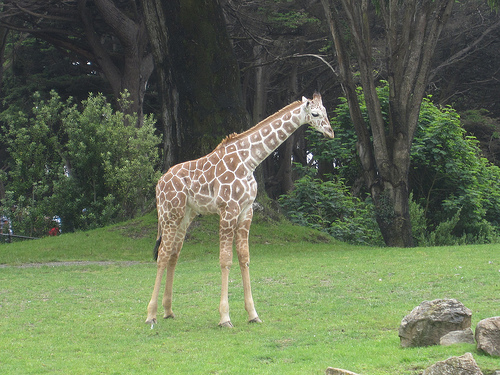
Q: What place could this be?
A: It is a zoo.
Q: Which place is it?
A: It is a zoo.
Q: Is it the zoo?
A: Yes, it is the zoo.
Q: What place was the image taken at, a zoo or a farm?
A: It was taken at a zoo.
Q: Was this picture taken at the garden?
A: No, the picture was taken in the zoo.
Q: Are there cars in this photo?
A: No, there are no cars.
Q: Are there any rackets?
A: No, there are no rackets.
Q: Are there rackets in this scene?
A: No, there are no rackets.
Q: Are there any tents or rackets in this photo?
A: No, there are no rackets or tents.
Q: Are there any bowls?
A: No, there are no bowls.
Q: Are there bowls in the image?
A: No, there are no bowls.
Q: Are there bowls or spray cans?
A: No, there are no bowls or spray cans.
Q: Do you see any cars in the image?
A: No, there are no cars.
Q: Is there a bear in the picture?
A: No, there are no bears.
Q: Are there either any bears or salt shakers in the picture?
A: No, there are no bears or salt shakers.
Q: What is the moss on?
A: The moss is on the tree.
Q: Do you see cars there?
A: No, there are no cars.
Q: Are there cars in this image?
A: No, there are no cars.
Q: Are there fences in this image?
A: Yes, there is a fence.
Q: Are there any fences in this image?
A: Yes, there is a fence.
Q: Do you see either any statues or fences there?
A: Yes, there is a fence.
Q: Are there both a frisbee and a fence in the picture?
A: No, there is a fence but no frisbees.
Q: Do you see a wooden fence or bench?
A: Yes, there is a wood fence.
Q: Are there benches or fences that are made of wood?
A: Yes, the fence is made of wood.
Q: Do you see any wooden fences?
A: Yes, there is a wood fence.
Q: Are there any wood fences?
A: Yes, there is a wood fence.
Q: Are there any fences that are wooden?
A: Yes, there is a fence that is wooden.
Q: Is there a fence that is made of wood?
A: Yes, there is a fence that is made of wood.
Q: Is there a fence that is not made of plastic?
A: Yes, there is a fence that is made of wood.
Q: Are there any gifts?
A: No, there are no gifts.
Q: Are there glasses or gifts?
A: No, there are no gifts or glasses.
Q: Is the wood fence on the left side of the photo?
A: Yes, the fence is on the left of the image.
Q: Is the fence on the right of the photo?
A: No, the fence is on the left of the image.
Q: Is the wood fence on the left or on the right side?
A: The fence is on the left of the image.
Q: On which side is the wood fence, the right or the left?
A: The fence is on the left of the image.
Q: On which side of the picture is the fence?
A: The fence is on the left of the image.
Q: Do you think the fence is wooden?
A: Yes, the fence is wooden.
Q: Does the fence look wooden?
A: Yes, the fence is wooden.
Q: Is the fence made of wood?
A: Yes, the fence is made of wood.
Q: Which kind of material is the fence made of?
A: The fence is made of wood.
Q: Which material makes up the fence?
A: The fence is made of wood.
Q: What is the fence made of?
A: The fence is made of wood.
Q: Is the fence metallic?
A: No, the fence is wooden.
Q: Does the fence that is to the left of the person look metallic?
A: No, the fence is wooden.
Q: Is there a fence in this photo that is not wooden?
A: No, there is a fence but it is wooden.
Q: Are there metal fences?
A: No, there is a fence but it is made of wood.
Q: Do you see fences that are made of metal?
A: No, there is a fence but it is made of wood.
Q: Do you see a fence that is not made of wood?
A: No, there is a fence but it is made of wood.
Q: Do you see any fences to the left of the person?
A: Yes, there is a fence to the left of the person.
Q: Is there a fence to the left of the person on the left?
A: Yes, there is a fence to the left of the person.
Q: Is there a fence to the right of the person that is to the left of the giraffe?
A: No, the fence is to the left of the person.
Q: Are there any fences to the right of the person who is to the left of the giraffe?
A: No, the fence is to the left of the person.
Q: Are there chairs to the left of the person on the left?
A: No, there is a fence to the left of the person.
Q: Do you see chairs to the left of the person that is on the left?
A: No, there is a fence to the left of the person.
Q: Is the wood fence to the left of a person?
A: Yes, the fence is to the left of a person.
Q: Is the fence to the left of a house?
A: No, the fence is to the left of a person.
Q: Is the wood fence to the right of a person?
A: No, the fence is to the left of a person.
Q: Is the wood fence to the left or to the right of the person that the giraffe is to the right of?
A: The fence is to the left of the person.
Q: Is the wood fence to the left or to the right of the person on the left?
A: The fence is to the left of the person.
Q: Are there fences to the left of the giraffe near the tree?
A: Yes, there is a fence to the left of the giraffe.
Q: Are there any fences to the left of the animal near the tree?
A: Yes, there is a fence to the left of the giraffe.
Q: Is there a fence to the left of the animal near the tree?
A: Yes, there is a fence to the left of the giraffe.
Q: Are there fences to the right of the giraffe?
A: No, the fence is to the left of the giraffe.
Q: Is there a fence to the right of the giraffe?
A: No, the fence is to the left of the giraffe.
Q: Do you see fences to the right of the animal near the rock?
A: No, the fence is to the left of the giraffe.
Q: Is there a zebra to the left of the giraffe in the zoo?
A: No, there is a fence to the left of the giraffe.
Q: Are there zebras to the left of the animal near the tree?
A: No, there is a fence to the left of the giraffe.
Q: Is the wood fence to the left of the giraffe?
A: Yes, the fence is to the left of the giraffe.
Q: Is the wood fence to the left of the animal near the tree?
A: Yes, the fence is to the left of the giraffe.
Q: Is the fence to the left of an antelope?
A: No, the fence is to the left of the giraffe.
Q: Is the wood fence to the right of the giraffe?
A: No, the fence is to the left of the giraffe.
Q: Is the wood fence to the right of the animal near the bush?
A: No, the fence is to the left of the giraffe.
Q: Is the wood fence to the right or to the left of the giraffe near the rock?
A: The fence is to the left of the giraffe.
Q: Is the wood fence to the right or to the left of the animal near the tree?
A: The fence is to the left of the giraffe.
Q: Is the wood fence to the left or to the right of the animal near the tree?
A: The fence is to the left of the giraffe.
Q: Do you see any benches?
A: No, there are no benches.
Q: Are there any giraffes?
A: Yes, there is a giraffe.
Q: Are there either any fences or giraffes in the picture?
A: Yes, there is a giraffe.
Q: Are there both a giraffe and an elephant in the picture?
A: No, there is a giraffe but no elephants.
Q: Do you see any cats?
A: No, there are no cats.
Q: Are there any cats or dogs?
A: No, there are no cats or dogs.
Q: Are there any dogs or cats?
A: No, there are no cats or dogs.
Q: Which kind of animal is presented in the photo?
A: The animal is a giraffe.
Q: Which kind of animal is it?
A: The animal is a giraffe.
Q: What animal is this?
A: This is a giraffe.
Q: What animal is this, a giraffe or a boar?
A: This is a giraffe.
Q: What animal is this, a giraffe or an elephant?
A: This is a giraffe.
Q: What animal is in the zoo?
A: The giraffe is in the zoo.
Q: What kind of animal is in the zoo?
A: The animal is a giraffe.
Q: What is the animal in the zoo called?
A: The animal is a giraffe.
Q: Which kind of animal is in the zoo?
A: The animal is a giraffe.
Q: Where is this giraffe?
A: The giraffe is in the zoo.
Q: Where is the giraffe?
A: The giraffe is in the zoo.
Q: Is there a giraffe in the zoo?
A: Yes, there is a giraffe in the zoo.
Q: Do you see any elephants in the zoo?
A: No, there is a giraffe in the zoo.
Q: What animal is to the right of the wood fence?
A: The animal is a giraffe.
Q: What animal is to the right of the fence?
A: The animal is a giraffe.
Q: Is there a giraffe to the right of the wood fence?
A: Yes, there is a giraffe to the right of the fence.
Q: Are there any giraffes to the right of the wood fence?
A: Yes, there is a giraffe to the right of the fence.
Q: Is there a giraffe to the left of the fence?
A: No, the giraffe is to the right of the fence.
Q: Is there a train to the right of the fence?
A: No, there is a giraffe to the right of the fence.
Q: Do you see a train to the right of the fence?
A: No, there is a giraffe to the right of the fence.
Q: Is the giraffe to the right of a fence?
A: Yes, the giraffe is to the right of a fence.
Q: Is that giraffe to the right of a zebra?
A: No, the giraffe is to the right of a fence.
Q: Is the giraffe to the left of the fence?
A: No, the giraffe is to the right of the fence.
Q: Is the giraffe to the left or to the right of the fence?
A: The giraffe is to the right of the fence.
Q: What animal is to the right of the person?
A: The animal is a giraffe.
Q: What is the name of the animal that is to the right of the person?
A: The animal is a giraffe.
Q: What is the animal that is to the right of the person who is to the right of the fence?
A: The animal is a giraffe.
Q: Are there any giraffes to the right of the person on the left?
A: Yes, there is a giraffe to the right of the person.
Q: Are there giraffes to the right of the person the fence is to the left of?
A: Yes, there is a giraffe to the right of the person.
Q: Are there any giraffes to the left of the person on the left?
A: No, the giraffe is to the right of the person.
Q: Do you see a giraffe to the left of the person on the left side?
A: No, the giraffe is to the right of the person.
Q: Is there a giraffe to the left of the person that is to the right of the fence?
A: No, the giraffe is to the right of the person.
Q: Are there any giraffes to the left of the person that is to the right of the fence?
A: No, the giraffe is to the right of the person.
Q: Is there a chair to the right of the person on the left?
A: No, there is a giraffe to the right of the person.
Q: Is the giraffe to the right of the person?
A: Yes, the giraffe is to the right of the person.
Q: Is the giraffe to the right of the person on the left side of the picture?
A: Yes, the giraffe is to the right of the person.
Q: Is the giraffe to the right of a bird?
A: No, the giraffe is to the right of the person.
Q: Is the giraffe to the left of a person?
A: No, the giraffe is to the right of a person.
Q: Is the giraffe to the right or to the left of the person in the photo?
A: The giraffe is to the right of the person.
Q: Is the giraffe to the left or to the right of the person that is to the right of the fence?
A: The giraffe is to the right of the person.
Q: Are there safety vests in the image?
A: No, there are no safety vests.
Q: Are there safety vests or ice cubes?
A: No, there are no safety vests or ice cubes.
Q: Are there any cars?
A: No, there are no cars.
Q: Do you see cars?
A: No, there are no cars.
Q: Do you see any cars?
A: No, there are no cars.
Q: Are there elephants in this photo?
A: No, there are no elephants.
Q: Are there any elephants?
A: No, there are no elephants.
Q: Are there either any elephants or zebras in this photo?
A: No, there are no elephants or zebras.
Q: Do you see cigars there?
A: No, there are no cigars.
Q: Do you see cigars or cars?
A: No, there are no cigars or cars.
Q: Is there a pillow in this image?
A: No, there are no pillows.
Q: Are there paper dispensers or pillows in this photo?
A: No, there are no pillows or paper dispensers.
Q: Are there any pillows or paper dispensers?
A: No, there are no pillows or paper dispensers.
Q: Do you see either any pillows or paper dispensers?
A: No, there are no pillows or paper dispensers.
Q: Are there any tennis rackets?
A: No, there are no tennis rackets.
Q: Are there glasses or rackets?
A: No, there are no rackets or glasses.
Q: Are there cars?
A: No, there are no cars.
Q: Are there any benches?
A: No, there are no benches.